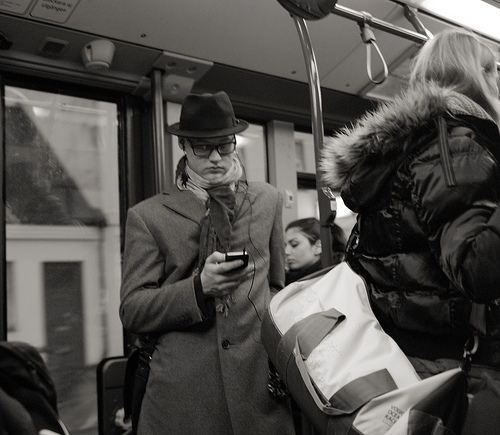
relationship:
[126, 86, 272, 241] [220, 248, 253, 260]
man using cellphone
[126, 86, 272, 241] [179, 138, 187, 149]
man listening to ear buds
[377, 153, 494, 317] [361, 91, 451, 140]
coat with fur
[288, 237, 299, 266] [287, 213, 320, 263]
face of a woman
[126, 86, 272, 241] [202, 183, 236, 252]
man wearing scarf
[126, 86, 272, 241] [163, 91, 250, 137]
man wearing hat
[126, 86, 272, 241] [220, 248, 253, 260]
man holding cellphone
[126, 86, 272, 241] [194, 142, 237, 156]
man wearing eyeglasses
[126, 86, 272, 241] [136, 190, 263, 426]
man wearing coat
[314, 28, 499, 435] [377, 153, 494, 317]
people wearing a coat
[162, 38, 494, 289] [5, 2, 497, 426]
people inside a train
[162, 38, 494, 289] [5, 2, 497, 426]
people riding a train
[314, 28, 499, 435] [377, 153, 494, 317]
people wearing coat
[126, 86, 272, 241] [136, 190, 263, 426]
man wearing a coat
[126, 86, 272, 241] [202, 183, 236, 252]
man wearing a scarf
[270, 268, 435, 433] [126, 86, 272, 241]
bag in front of man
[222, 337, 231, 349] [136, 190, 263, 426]
button on coat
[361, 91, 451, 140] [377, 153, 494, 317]
fur on coat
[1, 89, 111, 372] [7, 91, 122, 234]
house outside window